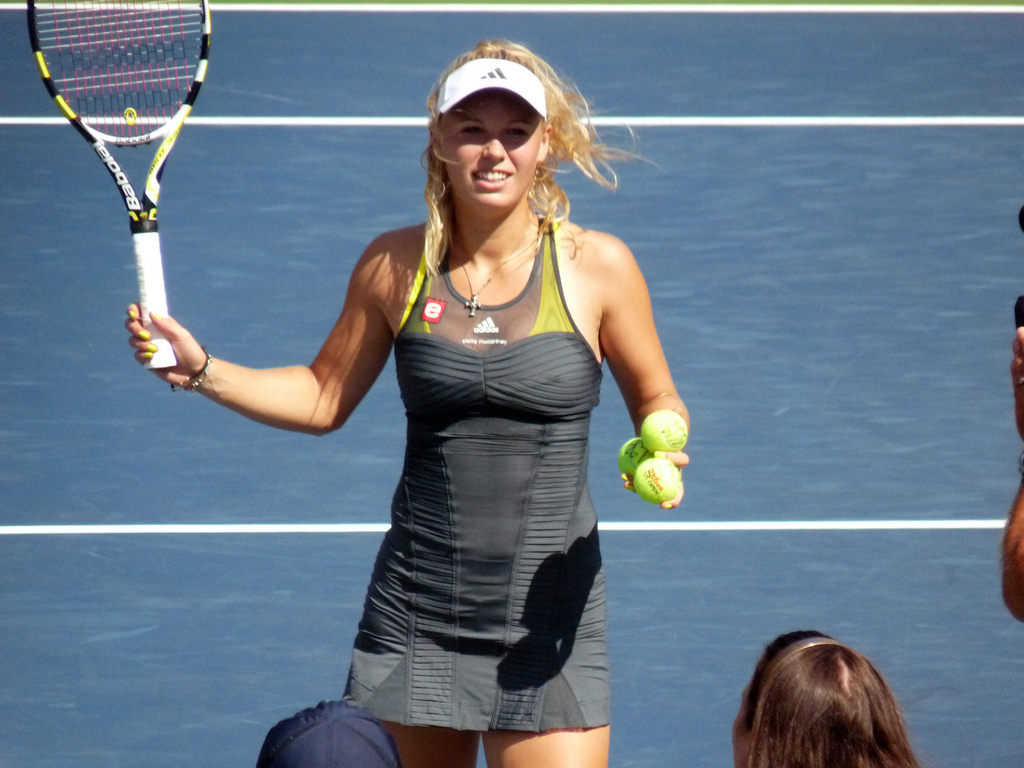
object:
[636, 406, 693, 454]
balls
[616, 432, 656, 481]
tennis ball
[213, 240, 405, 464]
right arm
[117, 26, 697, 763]
tennis player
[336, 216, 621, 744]
dress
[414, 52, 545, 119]
visor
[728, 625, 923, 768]
head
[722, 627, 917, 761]
woman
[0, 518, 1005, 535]
line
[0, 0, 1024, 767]
court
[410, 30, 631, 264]
hair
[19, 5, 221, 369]
racket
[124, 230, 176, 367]
handle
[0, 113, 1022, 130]
line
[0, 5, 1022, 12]
line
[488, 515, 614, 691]
shadow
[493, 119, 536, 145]
eye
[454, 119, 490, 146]
eye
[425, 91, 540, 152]
shadow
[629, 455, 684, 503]
balls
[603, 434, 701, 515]
hand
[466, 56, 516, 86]
logo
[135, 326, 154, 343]
fingernails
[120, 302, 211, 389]
hand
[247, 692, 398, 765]
baseball cap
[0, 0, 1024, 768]
ground